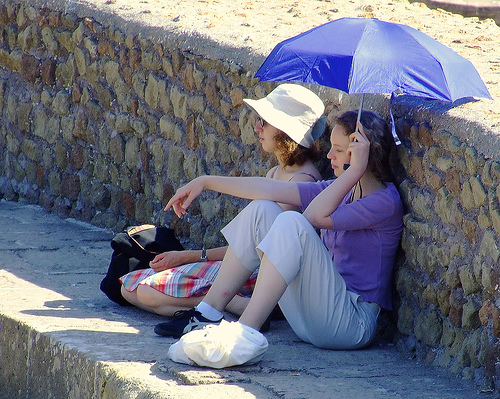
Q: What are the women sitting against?
A: Wall.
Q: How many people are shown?
A: Two.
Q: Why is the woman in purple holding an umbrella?
A: For shade.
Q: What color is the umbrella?
A: Purple.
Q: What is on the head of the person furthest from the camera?
A: Hat.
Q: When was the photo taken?
A: Daytime.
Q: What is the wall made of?
A: Stones.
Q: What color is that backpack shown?
A: Black.